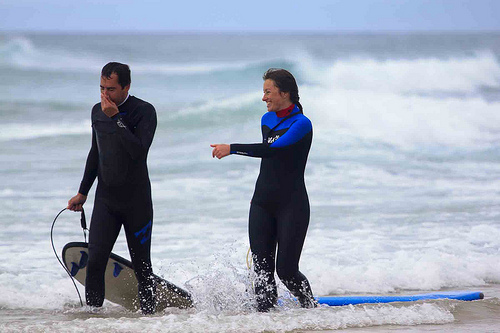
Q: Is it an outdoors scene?
A: Yes, it is outdoors.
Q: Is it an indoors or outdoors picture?
A: It is outdoors.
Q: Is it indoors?
A: No, it is outdoors.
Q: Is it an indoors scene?
A: No, it is outdoors.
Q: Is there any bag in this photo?
A: No, there are no bags.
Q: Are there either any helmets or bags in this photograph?
A: No, there are no bags or helmets.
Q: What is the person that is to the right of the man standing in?
A: The person is standing in the water.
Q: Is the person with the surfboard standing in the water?
A: Yes, the person is standing in the water.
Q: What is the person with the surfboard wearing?
A: The person is wearing a wet suit.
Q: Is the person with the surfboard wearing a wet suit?
A: Yes, the person is wearing a wet suit.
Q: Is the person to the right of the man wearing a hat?
A: No, the person is wearing a wet suit.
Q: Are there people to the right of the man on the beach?
A: Yes, there is a person to the right of the man.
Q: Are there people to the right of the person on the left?
A: Yes, there is a person to the right of the man.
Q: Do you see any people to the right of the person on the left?
A: Yes, there is a person to the right of the man.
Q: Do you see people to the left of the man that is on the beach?
A: No, the person is to the right of the man.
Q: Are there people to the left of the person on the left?
A: No, the person is to the right of the man.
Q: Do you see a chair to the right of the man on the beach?
A: No, there is a person to the right of the man.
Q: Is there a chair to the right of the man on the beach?
A: No, there is a person to the right of the man.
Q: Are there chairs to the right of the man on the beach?
A: No, there is a person to the right of the man.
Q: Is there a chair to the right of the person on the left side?
A: No, there is a person to the right of the man.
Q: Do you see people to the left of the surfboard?
A: Yes, there is a person to the left of the surfboard.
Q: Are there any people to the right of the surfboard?
A: No, the person is to the left of the surfboard.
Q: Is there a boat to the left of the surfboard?
A: No, there is a person to the left of the surfboard.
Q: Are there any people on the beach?
A: Yes, there is a person on the beach.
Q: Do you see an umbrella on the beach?
A: No, there is a person on the beach.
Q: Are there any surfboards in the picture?
A: Yes, there is a surfboard.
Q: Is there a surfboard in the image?
A: Yes, there is a surfboard.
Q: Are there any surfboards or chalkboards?
A: Yes, there is a surfboard.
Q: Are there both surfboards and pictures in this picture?
A: No, there is a surfboard but no pictures.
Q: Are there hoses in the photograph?
A: No, there are no hoses.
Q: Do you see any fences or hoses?
A: No, there are no hoses or fences.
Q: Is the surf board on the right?
A: Yes, the surf board is on the right of the image.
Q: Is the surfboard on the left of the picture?
A: No, the surfboard is on the right of the image.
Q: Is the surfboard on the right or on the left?
A: The surfboard is on the right of the image.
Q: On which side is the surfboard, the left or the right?
A: The surfboard is on the right of the image.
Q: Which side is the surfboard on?
A: The surfboard is on the right of the image.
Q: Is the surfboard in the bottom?
A: Yes, the surfboard is in the bottom of the image.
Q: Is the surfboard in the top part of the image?
A: No, the surfboard is in the bottom of the image.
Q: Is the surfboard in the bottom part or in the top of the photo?
A: The surfboard is in the bottom of the image.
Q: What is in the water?
A: The surfboard is in the water.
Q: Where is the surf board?
A: The surf board is in the water.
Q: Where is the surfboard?
A: The surf board is in the water.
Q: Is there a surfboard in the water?
A: Yes, there is a surfboard in the water.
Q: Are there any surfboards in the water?
A: Yes, there is a surfboard in the water.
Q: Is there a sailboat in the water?
A: No, there is a surfboard in the water.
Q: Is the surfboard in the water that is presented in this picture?
A: Yes, the surfboard is in the water.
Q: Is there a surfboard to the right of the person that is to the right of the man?
A: Yes, there is a surfboard to the right of the person.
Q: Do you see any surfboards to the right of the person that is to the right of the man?
A: Yes, there is a surfboard to the right of the person.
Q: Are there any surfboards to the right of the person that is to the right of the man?
A: Yes, there is a surfboard to the right of the person.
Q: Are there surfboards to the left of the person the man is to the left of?
A: No, the surfboard is to the right of the person.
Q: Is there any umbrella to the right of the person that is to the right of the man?
A: No, there is a surfboard to the right of the person.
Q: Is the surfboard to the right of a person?
A: Yes, the surfboard is to the right of a person.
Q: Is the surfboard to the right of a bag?
A: No, the surfboard is to the right of a person.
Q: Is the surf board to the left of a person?
A: No, the surf board is to the right of a person.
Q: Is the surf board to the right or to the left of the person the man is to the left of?
A: The surf board is to the right of the person.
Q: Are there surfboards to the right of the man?
A: Yes, there is a surfboard to the right of the man.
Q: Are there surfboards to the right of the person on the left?
A: Yes, there is a surfboard to the right of the man.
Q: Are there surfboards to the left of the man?
A: No, the surfboard is to the right of the man.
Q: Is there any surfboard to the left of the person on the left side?
A: No, the surfboard is to the right of the man.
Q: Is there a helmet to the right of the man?
A: No, there is a surfboard to the right of the man.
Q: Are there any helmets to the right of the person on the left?
A: No, there is a surfboard to the right of the man.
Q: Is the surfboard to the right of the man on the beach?
A: Yes, the surfboard is to the right of the man.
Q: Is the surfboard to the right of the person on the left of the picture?
A: Yes, the surfboard is to the right of the man.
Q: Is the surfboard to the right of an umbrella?
A: No, the surfboard is to the right of the man.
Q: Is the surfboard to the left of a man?
A: No, the surfboard is to the right of a man.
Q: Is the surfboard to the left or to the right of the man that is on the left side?
A: The surfboard is to the right of the man.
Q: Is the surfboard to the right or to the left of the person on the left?
A: The surfboard is to the right of the man.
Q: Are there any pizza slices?
A: No, there are no pizza slices.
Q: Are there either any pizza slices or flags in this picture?
A: No, there are no pizza slices or flags.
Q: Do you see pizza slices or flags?
A: No, there are no pizza slices or flags.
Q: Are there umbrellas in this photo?
A: No, there are no umbrellas.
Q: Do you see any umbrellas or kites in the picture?
A: No, there are no umbrellas or kites.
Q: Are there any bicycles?
A: No, there are no bicycles.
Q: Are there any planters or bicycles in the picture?
A: No, there are no bicycles or planters.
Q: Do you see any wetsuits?
A: Yes, there is a wetsuit.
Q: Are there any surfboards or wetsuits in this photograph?
A: Yes, there is a wetsuit.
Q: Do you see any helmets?
A: No, there are no helmets.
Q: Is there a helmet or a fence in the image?
A: No, there are no helmets or fences.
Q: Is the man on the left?
A: Yes, the man is on the left of the image.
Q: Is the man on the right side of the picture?
A: No, the man is on the left of the image.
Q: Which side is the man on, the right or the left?
A: The man is on the left of the image.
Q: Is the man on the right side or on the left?
A: The man is on the left of the image.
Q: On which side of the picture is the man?
A: The man is on the left of the image.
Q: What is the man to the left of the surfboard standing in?
A: The man is standing in the water.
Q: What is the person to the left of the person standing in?
A: The man is standing in the water.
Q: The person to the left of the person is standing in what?
A: The man is standing in the water.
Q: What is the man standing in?
A: The man is standing in the water.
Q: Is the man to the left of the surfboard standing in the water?
A: Yes, the man is standing in the water.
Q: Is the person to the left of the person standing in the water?
A: Yes, the man is standing in the water.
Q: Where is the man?
A: The man is on the beach.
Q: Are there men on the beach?
A: Yes, there is a man on the beach.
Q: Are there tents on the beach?
A: No, there is a man on the beach.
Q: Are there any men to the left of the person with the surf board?
A: Yes, there is a man to the left of the person.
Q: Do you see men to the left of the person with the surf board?
A: Yes, there is a man to the left of the person.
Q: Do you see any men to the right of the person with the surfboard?
A: No, the man is to the left of the person.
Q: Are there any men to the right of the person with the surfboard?
A: No, the man is to the left of the person.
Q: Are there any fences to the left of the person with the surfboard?
A: No, there is a man to the left of the person.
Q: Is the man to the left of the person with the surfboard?
A: Yes, the man is to the left of the person.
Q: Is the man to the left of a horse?
A: No, the man is to the left of the person.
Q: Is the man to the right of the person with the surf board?
A: No, the man is to the left of the person.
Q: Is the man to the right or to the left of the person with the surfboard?
A: The man is to the left of the person.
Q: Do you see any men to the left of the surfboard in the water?
A: Yes, there is a man to the left of the surfboard.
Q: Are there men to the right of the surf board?
A: No, the man is to the left of the surf board.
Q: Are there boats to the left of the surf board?
A: No, there is a man to the left of the surf board.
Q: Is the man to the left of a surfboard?
A: Yes, the man is to the left of a surfboard.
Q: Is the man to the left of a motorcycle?
A: No, the man is to the left of a surfboard.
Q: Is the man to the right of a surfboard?
A: No, the man is to the left of a surfboard.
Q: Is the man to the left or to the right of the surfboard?
A: The man is to the left of the surfboard.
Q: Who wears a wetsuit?
A: The man wears a wetsuit.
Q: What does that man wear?
A: The man wears a wetsuit.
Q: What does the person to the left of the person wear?
A: The man wears a wetsuit.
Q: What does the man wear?
A: The man wears a wetsuit.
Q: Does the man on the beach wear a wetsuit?
A: Yes, the man wears a wetsuit.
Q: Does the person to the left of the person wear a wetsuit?
A: Yes, the man wears a wetsuit.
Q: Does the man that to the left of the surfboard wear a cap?
A: No, the man wears a wetsuit.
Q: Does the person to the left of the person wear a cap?
A: No, the man wears a wetsuit.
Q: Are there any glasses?
A: No, there are no glasses.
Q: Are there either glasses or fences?
A: No, there are no glasses or fences.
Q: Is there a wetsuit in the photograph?
A: Yes, there is a wetsuit.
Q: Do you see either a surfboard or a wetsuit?
A: Yes, there is a wetsuit.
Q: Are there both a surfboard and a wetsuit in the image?
A: Yes, there are both a wetsuit and a surfboard.